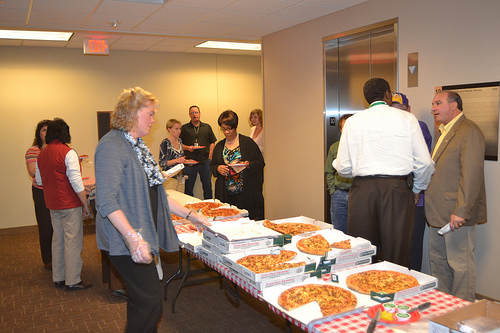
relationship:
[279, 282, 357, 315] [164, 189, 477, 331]
pizza on top of table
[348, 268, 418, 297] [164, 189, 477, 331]
pizza on top of table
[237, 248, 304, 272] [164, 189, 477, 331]
pizza on top of table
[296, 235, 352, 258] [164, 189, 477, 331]
pizza on top of table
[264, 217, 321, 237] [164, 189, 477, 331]
pizza on top of table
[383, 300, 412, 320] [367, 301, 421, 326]
sauce on top of plate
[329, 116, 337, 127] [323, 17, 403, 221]
floor number attached to elevator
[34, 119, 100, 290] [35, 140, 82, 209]
woman wearing vest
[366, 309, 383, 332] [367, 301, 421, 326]
knife leaning on plate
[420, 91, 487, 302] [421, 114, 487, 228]
man wearing sport coat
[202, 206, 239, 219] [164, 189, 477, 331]
pizza on top of table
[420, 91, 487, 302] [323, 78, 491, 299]
man standing in group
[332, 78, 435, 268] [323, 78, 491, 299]
man standing in group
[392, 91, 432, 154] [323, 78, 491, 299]
man standing in group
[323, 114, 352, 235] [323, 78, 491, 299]
man standing in group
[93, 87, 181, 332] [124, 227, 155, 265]
woman wearing glove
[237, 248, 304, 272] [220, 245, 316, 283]
pizza inside box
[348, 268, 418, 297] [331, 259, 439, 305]
pizza inside box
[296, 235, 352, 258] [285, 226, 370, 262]
pizza inside box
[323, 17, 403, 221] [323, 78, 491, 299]
elevator behind group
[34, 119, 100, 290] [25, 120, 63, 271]
woman talking to woman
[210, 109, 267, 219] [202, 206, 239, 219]
woman waiting for pizza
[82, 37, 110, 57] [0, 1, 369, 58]
exit sign attached to ceiling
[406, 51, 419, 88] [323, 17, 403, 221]
sign next to elevator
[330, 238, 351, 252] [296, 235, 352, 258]
slice os pizza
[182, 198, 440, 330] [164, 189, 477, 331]
pizzas on top of table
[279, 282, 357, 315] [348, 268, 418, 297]
pizza next to pizza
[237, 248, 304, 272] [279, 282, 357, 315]
pizza next to pizza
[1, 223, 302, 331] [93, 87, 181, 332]
floor beneath woman